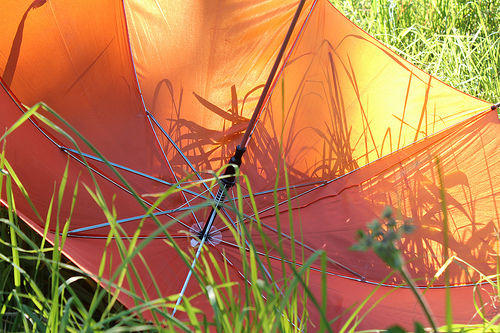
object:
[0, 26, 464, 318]
umbrella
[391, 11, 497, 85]
grass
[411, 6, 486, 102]
mowed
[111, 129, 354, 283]
spokes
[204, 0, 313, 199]
handle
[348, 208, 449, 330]
wildflower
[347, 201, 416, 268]
buds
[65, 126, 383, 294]
wires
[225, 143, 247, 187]
stem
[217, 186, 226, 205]
spring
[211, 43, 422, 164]
shadow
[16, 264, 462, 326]
fall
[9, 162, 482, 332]
ground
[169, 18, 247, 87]
fabric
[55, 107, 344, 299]
frame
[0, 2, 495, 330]
photo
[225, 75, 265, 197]
object